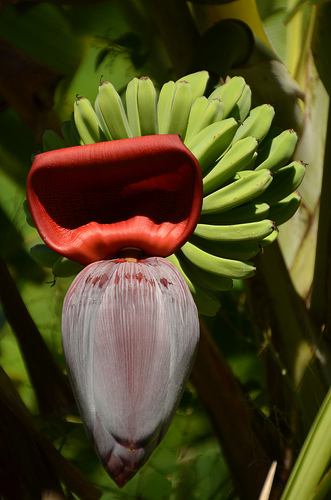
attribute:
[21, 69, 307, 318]
bananas — green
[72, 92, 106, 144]
bananas — green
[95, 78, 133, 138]
bananas — green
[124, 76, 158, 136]
bananas — green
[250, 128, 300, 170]
bananas — green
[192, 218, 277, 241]
bananas — green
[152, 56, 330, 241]
bananas — green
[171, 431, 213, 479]
leaves — green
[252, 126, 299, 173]
banana — green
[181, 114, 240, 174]
banana — green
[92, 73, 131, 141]
banana — green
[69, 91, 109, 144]
banana — green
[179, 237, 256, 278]
banana — green